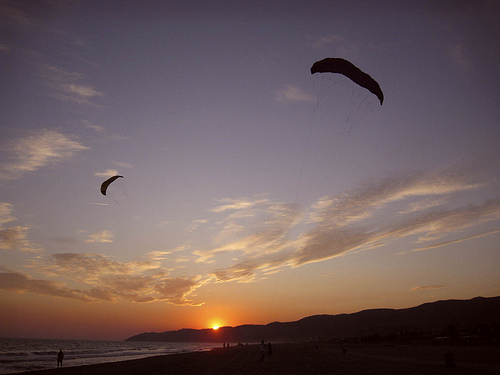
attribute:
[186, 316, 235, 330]
sunset — red, colorful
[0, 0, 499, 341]
sky — blue, light, dark, cloudy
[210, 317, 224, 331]
sun — low, setting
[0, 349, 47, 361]
waves — small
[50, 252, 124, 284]
cloud — white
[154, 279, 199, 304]
cloud — white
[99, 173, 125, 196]
parachute — black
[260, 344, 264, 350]
vest — white